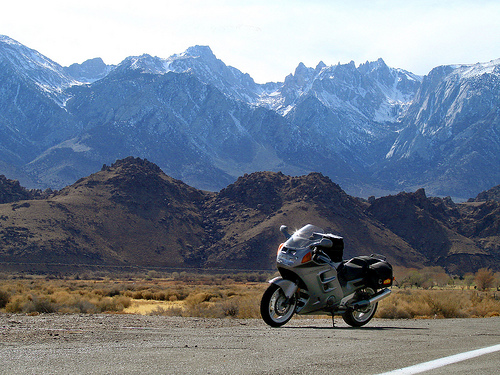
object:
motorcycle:
[258, 222, 401, 333]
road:
[1, 309, 500, 373]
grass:
[1, 274, 498, 318]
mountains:
[0, 28, 499, 198]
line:
[374, 341, 499, 375]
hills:
[1, 155, 500, 291]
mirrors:
[310, 237, 333, 249]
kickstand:
[330, 308, 337, 327]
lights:
[280, 245, 297, 257]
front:
[258, 223, 318, 327]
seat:
[337, 257, 375, 281]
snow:
[1, 34, 496, 125]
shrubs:
[0, 293, 236, 318]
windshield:
[284, 222, 325, 249]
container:
[366, 262, 396, 289]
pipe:
[351, 289, 392, 306]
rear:
[342, 255, 394, 329]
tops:
[0, 37, 498, 120]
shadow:
[286, 321, 426, 332]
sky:
[0, 1, 498, 74]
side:
[4, 312, 343, 350]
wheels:
[259, 278, 300, 329]